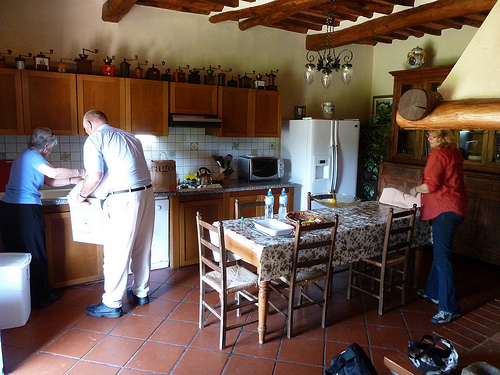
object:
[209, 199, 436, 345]
table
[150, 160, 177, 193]
bag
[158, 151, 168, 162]
handle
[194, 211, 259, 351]
chair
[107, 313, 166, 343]
tiles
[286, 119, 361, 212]
refrigerator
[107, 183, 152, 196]
belt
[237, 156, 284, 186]
microwave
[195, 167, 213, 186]
tea kettle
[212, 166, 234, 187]
knife block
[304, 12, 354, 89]
light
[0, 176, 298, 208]
counter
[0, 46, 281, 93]
coffee grinders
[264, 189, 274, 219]
bottles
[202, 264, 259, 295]
seat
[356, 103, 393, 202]
plant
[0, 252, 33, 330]
trash can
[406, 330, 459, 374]
helmet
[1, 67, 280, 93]
shelf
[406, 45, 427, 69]
jar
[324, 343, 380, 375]
bag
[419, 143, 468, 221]
shirt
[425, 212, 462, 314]
jeans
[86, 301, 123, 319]
sneakers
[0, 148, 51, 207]
shirt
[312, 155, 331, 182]
icemaker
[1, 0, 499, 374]
kitchen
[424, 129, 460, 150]
hair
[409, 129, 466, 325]
woman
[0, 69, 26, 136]
cabinets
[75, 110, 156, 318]
person